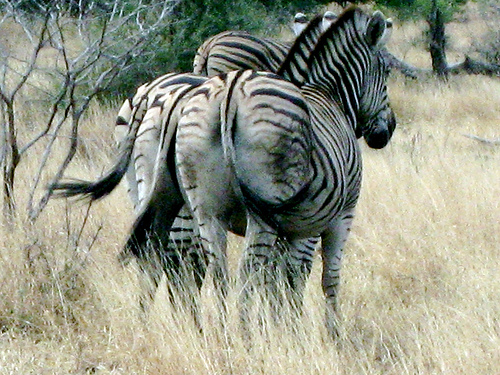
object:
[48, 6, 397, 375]
zebra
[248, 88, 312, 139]
stripe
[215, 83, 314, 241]
tail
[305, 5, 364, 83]
hair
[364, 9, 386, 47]
ear